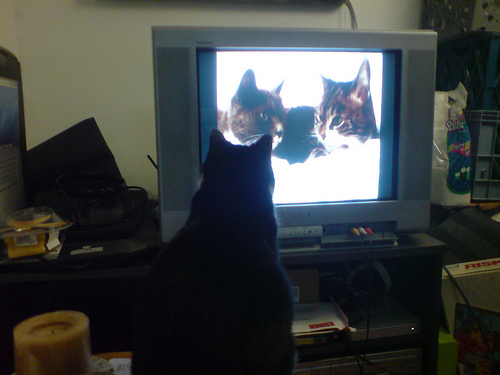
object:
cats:
[218, 58, 379, 162]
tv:
[151, 25, 438, 243]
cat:
[126, 130, 297, 373]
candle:
[11, 309, 96, 373]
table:
[1, 340, 132, 375]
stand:
[5, 234, 446, 375]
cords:
[350, 226, 386, 332]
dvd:
[1, 210, 62, 265]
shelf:
[0, 224, 450, 284]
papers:
[291, 294, 350, 341]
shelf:
[273, 241, 441, 368]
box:
[437, 257, 500, 343]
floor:
[416, 309, 499, 375]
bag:
[429, 83, 473, 207]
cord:
[144, 152, 159, 171]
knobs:
[278, 227, 314, 237]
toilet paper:
[431, 125, 472, 207]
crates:
[421, 0, 498, 209]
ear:
[207, 128, 227, 148]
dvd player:
[345, 295, 419, 345]